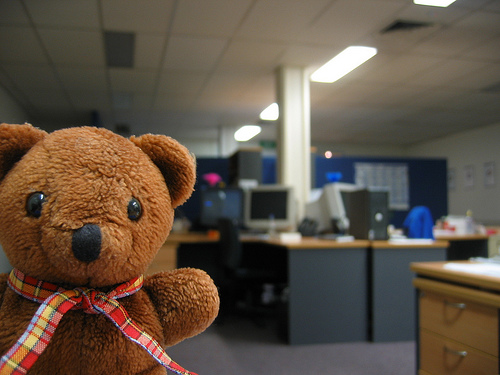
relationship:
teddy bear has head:
[1, 124, 220, 375] [0, 124, 197, 288]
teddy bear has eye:
[1, 124, 220, 375] [25, 191, 45, 217]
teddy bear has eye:
[1, 124, 220, 375] [128, 198, 142, 221]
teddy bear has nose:
[1, 124, 220, 375] [71, 224, 101, 263]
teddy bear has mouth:
[1, 124, 220, 375] [34, 226, 135, 286]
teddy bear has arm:
[1, 124, 220, 375] [142, 267, 220, 346]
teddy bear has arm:
[1, 124, 220, 375] [3, 272, 11, 298]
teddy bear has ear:
[1, 124, 220, 375] [132, 132, 197, 208]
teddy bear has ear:
[1, 124, 220, 375] [0, 122, 49, 179]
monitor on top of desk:
[243, 187, 292, 228] [242, 232, 370, 345]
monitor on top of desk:
[306, 182, 358, 227] [370, 239, 449, 342]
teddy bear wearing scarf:
[1, 124, 220, 375] [0, 267, 197, 374]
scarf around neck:
[0, 267, 197, 374] [6, 267, 146, 316]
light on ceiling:
[311, 45, 376, 85] [1, 1, 500, 155]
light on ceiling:
[259, 102, 279, 121] [1, 1, 500, 155]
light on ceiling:
[233, 125, 261, 141] [1, 1, 500, 155]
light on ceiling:
[414, 1, 456, 8] [1, 1, 500, 155]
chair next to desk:
[217, 217, 278, 334] [242, 232, 370, 345]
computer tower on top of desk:
[348, 191, 388, 241] [370, 239, 449, 342]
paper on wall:
[463, 163, 473, 189] [406, 120, 499, 225]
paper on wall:
[446, 166, 455, 188] [406, 120, 499, 225]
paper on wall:
[482, 160, 495, 185] [406, 120, 499, 225]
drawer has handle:
[419, 289, 500, 355] [444, 300, 465, 308]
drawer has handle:
[417, 327, 498, 374] [444, 344, 466, 354]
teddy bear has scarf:
[1, 124, 220, 375] [0, 267, 197, 374]